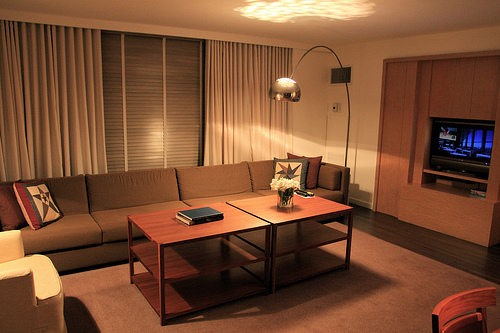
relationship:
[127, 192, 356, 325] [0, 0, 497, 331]
table in living room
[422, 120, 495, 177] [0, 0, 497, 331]
television in living room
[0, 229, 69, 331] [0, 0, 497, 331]
chair in living room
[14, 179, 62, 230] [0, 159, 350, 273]
pillow on couch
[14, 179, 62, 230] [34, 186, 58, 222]
pillow has a star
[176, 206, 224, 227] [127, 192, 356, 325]
book on table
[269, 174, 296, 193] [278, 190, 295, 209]
flowers in pot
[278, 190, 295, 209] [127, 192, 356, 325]
pot on table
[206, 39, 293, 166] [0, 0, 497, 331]
curtains in living room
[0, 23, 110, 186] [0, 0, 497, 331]
curtains in living room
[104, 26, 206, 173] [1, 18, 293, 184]
blinds on window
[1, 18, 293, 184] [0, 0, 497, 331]
window in living room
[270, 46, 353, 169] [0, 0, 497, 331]
lamp in living room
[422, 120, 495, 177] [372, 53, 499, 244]
television on wall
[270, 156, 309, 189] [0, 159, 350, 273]
pillow on couch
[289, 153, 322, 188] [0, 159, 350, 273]
pillow on couch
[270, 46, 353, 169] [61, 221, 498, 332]
lamp on floor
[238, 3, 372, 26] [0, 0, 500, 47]
reflection on ceiling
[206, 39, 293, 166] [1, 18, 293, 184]
curtains cover window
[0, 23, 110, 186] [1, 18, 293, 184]
curtains cover window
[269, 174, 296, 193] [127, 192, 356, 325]
flowers on table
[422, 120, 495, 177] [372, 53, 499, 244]
television inside entertainment center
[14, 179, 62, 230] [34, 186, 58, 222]
pillow has star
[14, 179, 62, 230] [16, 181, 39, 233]
pillow has trim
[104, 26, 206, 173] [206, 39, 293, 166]
blinds between curtains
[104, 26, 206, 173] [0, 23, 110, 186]
blinds between curtains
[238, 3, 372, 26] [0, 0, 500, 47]
light on ceiling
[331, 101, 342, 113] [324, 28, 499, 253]
thermostat on wall